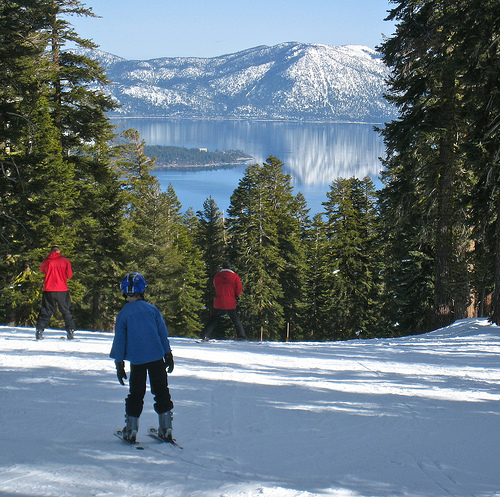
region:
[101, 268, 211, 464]
child on skis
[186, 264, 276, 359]
skier in a red jacket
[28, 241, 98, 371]
skier in a red jacket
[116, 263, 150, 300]
blue and black helmet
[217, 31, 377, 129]
snow covered mountain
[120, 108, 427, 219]
lake surrounded by snowy moutains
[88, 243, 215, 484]
kid in a blue jacket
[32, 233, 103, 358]
skier in black pants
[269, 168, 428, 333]
green trees near a lake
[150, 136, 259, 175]
islet in a lake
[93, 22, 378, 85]
mountain against the sky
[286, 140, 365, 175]
reflection on the water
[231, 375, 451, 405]
shadows of the trees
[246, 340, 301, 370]
snow on the ground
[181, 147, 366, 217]
trees against the water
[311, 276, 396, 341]
branches of the trees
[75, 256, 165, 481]
skier on the slope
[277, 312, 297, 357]
trunk of the tree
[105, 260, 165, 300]
ski helmet on boy's head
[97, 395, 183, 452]
ski boots on the boy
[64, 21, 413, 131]
Mountain range in the background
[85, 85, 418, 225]
Very remote mountain lake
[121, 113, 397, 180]
Reflection of mountains in the lake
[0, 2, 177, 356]
Large trees to the left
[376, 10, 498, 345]
Large trees to the left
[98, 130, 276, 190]
Piece of land in the lake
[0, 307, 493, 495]
Snow on the ground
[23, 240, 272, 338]
Two men with red jackets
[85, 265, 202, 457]
Young person with blue jacket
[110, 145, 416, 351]
Trees in the center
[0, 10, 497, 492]
skiers standing in the snow looking at a lake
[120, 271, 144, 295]
a girl's helmet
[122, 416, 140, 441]
a girl's ski boot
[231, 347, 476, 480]
snow on the ground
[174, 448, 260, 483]
ski tracks in the snow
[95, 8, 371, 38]
a pale blue sky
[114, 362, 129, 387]
a girl's gloved hand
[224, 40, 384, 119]
a snow capped mountain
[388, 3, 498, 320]
a large pine tree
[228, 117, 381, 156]
the reflection of a mountain in a lake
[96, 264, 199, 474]
little kid on skis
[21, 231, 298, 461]
group of people skiing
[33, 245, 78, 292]
read sweatshirt with a hood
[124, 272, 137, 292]
black stripe on the blue helmet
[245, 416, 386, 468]
shadow on the snow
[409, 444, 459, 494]
two thin tracks in the snow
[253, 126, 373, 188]
mountain reflected in the water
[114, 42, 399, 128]
large mountain covered in snow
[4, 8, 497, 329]
numerous tall dark green trees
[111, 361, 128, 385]
black glove